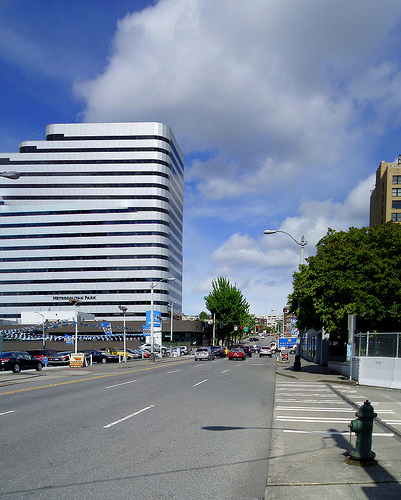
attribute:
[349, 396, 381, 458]
fire hydrant — green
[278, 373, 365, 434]
crosswalk — white, pattern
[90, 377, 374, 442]
street — concrete, section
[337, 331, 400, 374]
fence — wire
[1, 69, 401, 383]
background — white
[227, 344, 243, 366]
car — red, driving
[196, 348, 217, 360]
car — silver, parked, grey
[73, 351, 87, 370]
sign — yellow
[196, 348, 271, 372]
cars — many, driving, stopped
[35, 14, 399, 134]
sky — blue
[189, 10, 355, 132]
clouds — white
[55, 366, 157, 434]
lines — white, yellow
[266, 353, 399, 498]
sidewalk — section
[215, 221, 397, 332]
trees — green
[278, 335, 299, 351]
sign — blue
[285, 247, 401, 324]
tree — leafy, green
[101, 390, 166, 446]
line — white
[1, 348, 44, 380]
car — black, parked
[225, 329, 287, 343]
traffic lights — bank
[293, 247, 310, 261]
pole — gray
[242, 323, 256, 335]
sign — green, traffic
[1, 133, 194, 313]
building — large, on left, white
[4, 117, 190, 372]
honda dealership — on left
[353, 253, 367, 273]
leaves — green